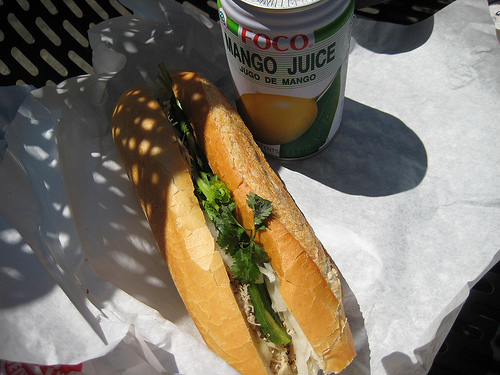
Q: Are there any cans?
A: Yes, there is a can.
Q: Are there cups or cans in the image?
A: Yes, there is a can.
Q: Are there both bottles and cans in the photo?
A: No, there is a can but no bottles.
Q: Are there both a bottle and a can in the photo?
A: No, there is a can but no bottles.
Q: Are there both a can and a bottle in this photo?
A: No, there is a can but no bottles.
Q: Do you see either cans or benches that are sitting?
A: Yes, the can is sitting.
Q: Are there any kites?
A: No, there are no kites.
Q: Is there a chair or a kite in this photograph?
A: No, there are no kites or chairs.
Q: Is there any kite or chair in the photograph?
A: No, there are no kites or chairs.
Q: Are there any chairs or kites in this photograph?
A: No, there are no kites or chairs.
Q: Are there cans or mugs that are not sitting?
A: No, there is a can but it is sitting.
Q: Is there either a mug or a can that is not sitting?
A: No, there is a can but it is sitting.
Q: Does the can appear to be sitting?
A: Yes, the can is sitting.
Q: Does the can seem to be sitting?
A: Yes, the can is sitting.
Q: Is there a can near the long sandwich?
A: Yes, there is a can near the sandwich.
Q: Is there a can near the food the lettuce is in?
A: Yes, there is a can near the sandwich.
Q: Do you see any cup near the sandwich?
A: No, there is a can near the sandwich.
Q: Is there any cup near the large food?
A: No, there is a can near the sandwich.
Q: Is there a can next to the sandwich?
A: Yes, there is a can next to the sandwich.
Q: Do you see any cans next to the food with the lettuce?
A: Yes, there is a can next to the sandwich.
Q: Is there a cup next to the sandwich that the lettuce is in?
A: No, there is a can next to the sandwich.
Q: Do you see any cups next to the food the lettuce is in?
A: No, there is a can next to the sandwich.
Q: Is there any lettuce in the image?
A: Yes, there is lettuce.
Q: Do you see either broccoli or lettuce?
A: Yes, there is lettuce.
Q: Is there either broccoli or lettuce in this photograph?
A: Yes, there is lettuce.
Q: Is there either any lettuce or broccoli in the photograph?
A: Yes, there is lettuce.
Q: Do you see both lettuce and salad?
A: No, there is lettuce but no salad.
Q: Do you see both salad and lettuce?
A: No, there is lettuce but no salad.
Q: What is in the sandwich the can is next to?
A: The lettuce is in the sandwich.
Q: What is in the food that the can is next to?
A: The lettuce is in the sandwich.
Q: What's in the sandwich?
A: The lettuce is in the sandwich.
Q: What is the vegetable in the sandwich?
A: The vegetable is lettuce.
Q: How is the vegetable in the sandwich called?
A: The vegetable is lettuce.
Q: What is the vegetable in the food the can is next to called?
A: The vegetable is lettuce.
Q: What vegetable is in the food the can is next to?
A: The vegetable is lettuce.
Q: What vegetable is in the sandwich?
A: The vegetable is lettuce.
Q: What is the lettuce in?
A: The lettuce is in the sandwich.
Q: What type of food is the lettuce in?
A: The lettuce is in the sandwich.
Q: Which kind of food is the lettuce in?
A: The lettuce is in the sandwich.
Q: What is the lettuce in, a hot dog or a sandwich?
A: The lettuce is in a sandwich.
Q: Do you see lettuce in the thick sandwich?
A: Yes, there is lettuce in the sandwich.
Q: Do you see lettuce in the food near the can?
A: Yes, there is lettuce in the sandwich.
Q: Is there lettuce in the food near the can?
A: Yes, there is lettuce in the sandwich.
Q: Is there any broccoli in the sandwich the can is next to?
A: No, there is lettuce in the sandwich.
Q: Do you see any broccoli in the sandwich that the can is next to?
A: No, there is lettuce in the sandwich.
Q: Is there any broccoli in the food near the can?
A: No, there is lettuce in the sandwich.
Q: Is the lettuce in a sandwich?
A: Yes, the lettuce is in a sandwich.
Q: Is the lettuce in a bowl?
A: No, the lettuce is in a sandwich.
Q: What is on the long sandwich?
A: The lettuce is on the sandwich.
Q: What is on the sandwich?
A: The lettuce is on the sandwich.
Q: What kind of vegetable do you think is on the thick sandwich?
A: The vegetable is lettuce.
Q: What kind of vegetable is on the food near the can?
A: The vegetable is lettuce.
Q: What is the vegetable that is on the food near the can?
A: The vegetable is lettuce.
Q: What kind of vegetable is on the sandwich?
A: The vegetable is lettuce.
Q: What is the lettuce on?
A: The lettuce is on the sandwich.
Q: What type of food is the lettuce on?
A: The lettuce is on the sandwich.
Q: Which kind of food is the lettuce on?
A: The lettuce is on the sandwich.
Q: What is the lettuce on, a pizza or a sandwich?
A: The lettuce is on a sandwich.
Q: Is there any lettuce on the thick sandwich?
A: Yes, there is lettuce on the sandwich.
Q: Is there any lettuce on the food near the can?
A: Yes, there is lettuce on the sandwich.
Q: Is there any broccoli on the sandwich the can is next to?
A: No, there is lettuce on the sandwich.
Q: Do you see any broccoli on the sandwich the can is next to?
A: No, there is lettuce on the sandwich.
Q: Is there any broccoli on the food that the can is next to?
A: No, there is lettuce on the sandwich.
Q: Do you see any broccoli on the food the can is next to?
A: No, there is lettuce on the sandwich.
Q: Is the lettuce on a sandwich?
A: Yes, the lettuce is on a sandwich.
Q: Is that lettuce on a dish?
A: No, the lettuce is on a sandwich.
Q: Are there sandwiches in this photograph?
A: Yes, there is a sandwich.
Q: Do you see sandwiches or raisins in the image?
A: Yes, there is a sandwich.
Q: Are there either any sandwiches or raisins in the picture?
A: Yes, there is a sandwich.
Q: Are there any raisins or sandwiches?
A: Yes, there is a sandwich.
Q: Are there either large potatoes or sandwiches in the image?
A: Yes, there is a large sandwich.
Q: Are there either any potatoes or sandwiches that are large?
A: Yes, the sandwich is large.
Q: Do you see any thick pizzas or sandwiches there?
A: Yes, there is a thick sandwich.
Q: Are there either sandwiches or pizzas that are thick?
A: Yes, the sandwich is thick.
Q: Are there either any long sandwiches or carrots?
A: Yes, there is a long sandwich.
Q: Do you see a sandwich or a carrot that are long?
A: Yes, the sandwich is long.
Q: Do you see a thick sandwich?
A: Yes, there is a thick sandwich.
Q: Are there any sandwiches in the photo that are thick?
A: Yes, there is a sandwich that is thick.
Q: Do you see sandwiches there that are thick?
A: Yes, there is a sandwich that is thick.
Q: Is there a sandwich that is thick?
A: Yes, there is a sandwich that is thick.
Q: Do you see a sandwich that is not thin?
A: Yes, there is a thick sandwich.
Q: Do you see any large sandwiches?
A: Yes, there is a large sandwich.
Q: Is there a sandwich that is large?
A: Yes, there is a sandwich that is large.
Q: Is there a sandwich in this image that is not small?
A: Yes, there is a large sandwich.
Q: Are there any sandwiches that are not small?
A: Yes, there is a large sandwich.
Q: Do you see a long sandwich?
A: Yes, there is a long sandwich.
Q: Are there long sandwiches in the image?
A: Yes, there is a long sandwich.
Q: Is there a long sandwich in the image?
A: Yes, there is a long sandwich.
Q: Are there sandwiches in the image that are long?
A: Yes, there is a sandwich that is long.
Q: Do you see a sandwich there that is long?
A: Yes, there is a sandwich that is long.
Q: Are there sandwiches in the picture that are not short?
A: Yes, there is a long sandwich.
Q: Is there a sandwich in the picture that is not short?
A: Yes, there is a long sandwich.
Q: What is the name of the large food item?
A: The food item is a sandwich.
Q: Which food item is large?
A: The food item is a sandwich.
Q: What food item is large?
A: The food item is a sandwich.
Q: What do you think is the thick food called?
A: The food is a sandwich.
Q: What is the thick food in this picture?
A: The food is a sandwich.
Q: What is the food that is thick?
A: The food is a sandwich.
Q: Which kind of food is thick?
A: The food is a sandwich.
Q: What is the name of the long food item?
A: The food item is a sandwich.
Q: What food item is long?
A: The food item is a sandwich.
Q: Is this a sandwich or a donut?
A: This is a sandwich.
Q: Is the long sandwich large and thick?
A: Yes, the sandwich is large and thick.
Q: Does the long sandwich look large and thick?
A: Yes, the sandwich is large and thick.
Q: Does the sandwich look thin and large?
A: No, the sandwich is large but thick.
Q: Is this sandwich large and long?
A: Yes, the sandwich is large and long.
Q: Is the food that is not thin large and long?
A: Yes, the sandwich is large and long.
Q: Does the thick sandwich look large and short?
A: No, the sandwich is large but long.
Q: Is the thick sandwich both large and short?
A: No, the sandwich is large but long.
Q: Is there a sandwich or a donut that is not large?
A: No, there is a sandwich but it is large.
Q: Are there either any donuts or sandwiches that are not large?
A: No, there is a sandwich but it is large.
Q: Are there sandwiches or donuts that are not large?
A: No, there is a sandwich but it is large.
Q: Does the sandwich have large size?
A: Yes, the sandwich is large.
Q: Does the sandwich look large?
A: Yes, the sandwich is large.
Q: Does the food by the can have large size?
A: Yes, the sandwich is large.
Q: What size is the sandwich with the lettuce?
A: The sandwich is large.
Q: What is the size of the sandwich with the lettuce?
A: The sandwich is large.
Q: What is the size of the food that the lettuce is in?
A: The sandwich is large.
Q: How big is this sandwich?
A: The sandwich is large.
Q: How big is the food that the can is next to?
A: The sandwich is large.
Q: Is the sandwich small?
A: No, the sandwich is large.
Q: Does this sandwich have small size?
A: No, the sandwich is large.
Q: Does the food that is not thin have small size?
A: No, the sandwich is large.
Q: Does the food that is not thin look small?
A: No, the sandwich is large.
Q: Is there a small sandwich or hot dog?
A: No, there is a sandwich but it is large.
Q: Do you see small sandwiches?
A: No, there is a sandwich but it is large.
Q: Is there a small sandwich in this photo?
A: No, there is a sandwich but it is large.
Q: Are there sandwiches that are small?
A: No, there is a sandwich but it is large.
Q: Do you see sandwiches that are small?
A: No, there is a sandwich but it is large.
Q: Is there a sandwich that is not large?
A: No, there is a sandwich but it is large.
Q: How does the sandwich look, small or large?
A: The sandwich is large.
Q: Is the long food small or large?
A: The sandwich is large.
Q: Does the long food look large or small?
A: The sandwich is large.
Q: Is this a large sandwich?
A: Yes, this is a large sandwich.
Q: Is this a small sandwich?
A: No, this is a large sandwich.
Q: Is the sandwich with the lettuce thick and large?
A: Yes, the sandwich is thick and large.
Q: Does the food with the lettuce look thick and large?
A: Yes, the sandwich is thick and large.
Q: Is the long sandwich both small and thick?
A: No, the sandwich is thick but large.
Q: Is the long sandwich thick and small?
A: No, the sandwich is thick but large.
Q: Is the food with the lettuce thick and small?
A: No, the sandwich is thick but large.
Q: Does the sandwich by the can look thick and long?
A: Yes, the sandwich is thick and long.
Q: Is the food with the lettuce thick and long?
A: Yes, the sandwich is thick and long.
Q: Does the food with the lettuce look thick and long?
A: Yes, the sandwich is thick and long.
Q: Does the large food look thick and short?
A: No, the sandwich is thick but long.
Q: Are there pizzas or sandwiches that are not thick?
A: No, there is a sandwich but it is thick.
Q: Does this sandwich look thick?
A: Yes, the sandwich is thick.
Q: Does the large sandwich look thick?
A: Yes, the sandwich is thick.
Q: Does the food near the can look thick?
A: Yes, the sandwich is thick.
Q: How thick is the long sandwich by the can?
A: The sandwich is thick.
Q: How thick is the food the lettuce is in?
A: The sandwich is thick.